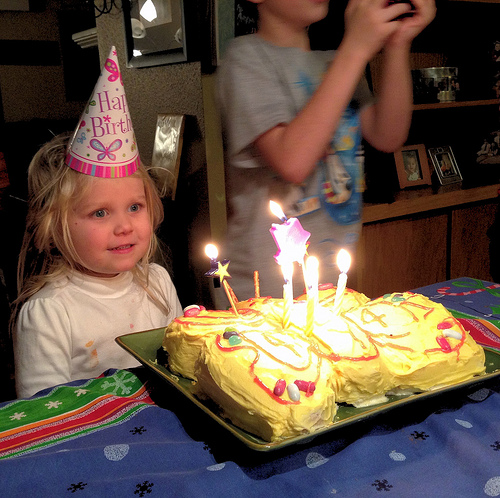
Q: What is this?
A: A birthday party.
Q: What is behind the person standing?
A: A bookcase.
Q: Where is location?
A: In a house.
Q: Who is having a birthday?
A: A little girl.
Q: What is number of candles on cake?
A: Four.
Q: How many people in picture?
A: Two.